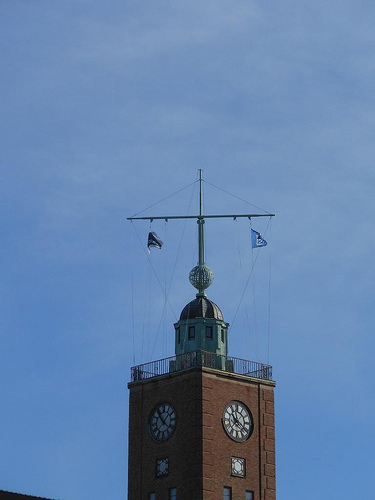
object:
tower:
[113, 163, 288, 500]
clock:
[220, 398, 257, 443]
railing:
[126, 349, 274, 394]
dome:
[172, 293, 231, 331]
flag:
[145, 229, 165, 253]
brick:
[203, 413, 213, 426]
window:
[218, 482, 235, 499]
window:
[166, 484, 178, 499]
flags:
[249, 227, 270, 251]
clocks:
[145, 399, 180, 444]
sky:
[0, 0, 195, 177]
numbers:
[234, 428, 240, 440]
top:
[126, 325, 284, 389]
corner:
[268, 380, 282, 499]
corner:
[195, 363, 210, 497]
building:
[119, 169, 280, 498]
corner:
[121, 364, 138, 498]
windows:
[243, 488, 254, 500]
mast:
[124, 167, 273, 262]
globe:
[188, 261, 216, 291]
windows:
[147, 492, 157, 499]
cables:
[228, 265, 252, 333]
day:
[74, 0, 343, 126]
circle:
[187, 262, 216, 293]